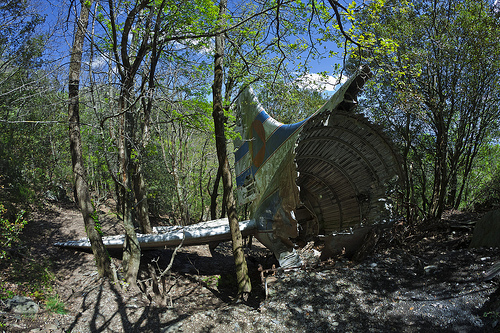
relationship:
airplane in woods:
[37, 65, 446, 270] [25, 41, 191, 197]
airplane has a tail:
[37, 65, 446, 270] [47, 217, 236, 261]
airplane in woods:
[37, 65, 405, 270] [25, 41, 191, 197]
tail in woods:
[47, 217, 236, 261] [25, 41, 191, 197]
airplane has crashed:
[37, 65, 405, 270] [288, 149, 378, 242]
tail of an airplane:
[47, 217, 236, 261] [37, 65, 446, 270]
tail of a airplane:
[47, 217, 236, 261] [37, 65, 405, 270]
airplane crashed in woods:
[37, 65, 405, 270] [25, 41, 191, 197]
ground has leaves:
[278, 281, 392, 328] [349, 8, 409, 29]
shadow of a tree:
[295, 267, 451, 321] [97, 11, 152, 166]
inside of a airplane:
[310, 157, 335, 192] [37, 65, 405, 270]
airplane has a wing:
[37, 65, 405, 270] [226, 93, 272, 152]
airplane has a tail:
[37, 65, 405, 270] [47, 217, 236, 261]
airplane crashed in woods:
[37, 65, 446, 270] [25, 41, 191, 197]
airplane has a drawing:
[37, 65, 405, 270] [243, 119, 276, 169]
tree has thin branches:
[97, 11, 152, 166] [269, 15, 318, 70]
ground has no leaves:
[278, 281, 392, 328] [349, 8, 409, 29]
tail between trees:
[47, 217, 236, 261] [357, 11, 494, 119]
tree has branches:
[97, 11, 152, 166] [170, 21, 274, 54]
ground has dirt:
[278, 281, 392, 328] [264, 266, 310, 294]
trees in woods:
[357, 11, 494, 119] [25, 41, 191, 197]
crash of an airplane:
[288, 232, 357, 269] [37, 65, 446, 270]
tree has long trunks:
[97, 11, 152, 166] [203, 42, 232, 173]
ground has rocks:
[278, 281, 392, 328] [429, 247, 491, 277]